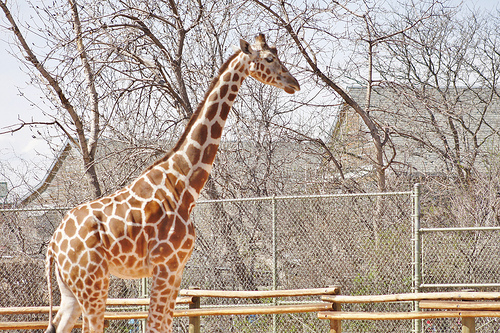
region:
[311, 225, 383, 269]
a gray fence with poles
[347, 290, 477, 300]
brown bleachers near fence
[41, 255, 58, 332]
the tail on giraffe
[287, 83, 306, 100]
mouth on the giraffe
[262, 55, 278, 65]
an eye on the giraffe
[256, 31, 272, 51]
one of the giraffe's ears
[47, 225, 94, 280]
hind area of giraffe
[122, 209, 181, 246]
portion of giraffe's spots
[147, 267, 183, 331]
front legs of giraffe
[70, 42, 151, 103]
some bare tree branches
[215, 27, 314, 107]
head of a giraffe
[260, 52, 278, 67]
eye of a giraffe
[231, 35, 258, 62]
ear of a giraffe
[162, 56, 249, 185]
neck of a giraffe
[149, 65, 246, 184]
long neck of a giraffe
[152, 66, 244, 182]
spotted neck of a giraffe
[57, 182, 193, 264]
body of a giraffe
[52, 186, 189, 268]
spotted body of a giraffe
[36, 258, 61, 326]
tail of a giraffe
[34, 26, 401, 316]
giraffe outside in daylight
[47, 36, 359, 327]
large giraffe standing in enclosure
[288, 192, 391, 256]
metal fence enclosure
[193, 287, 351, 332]
fence made of brown wood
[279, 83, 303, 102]
mouth of giraffe is slightly open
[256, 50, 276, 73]
side eye of giraffe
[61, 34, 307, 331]
giraffe is looking right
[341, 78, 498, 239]
house is in background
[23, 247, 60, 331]
tail of orange and cream giraffe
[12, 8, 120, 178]
trees without any leaves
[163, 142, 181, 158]
mohawk hair of giraffe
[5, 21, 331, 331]
a young adult giraffe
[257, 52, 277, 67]
the giraffe's right eye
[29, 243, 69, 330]
the tail of the giraffe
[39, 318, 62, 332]
ball looking thing on the bottom of the giraffe's tail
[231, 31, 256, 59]
the giraffe's right ear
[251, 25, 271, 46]
horn on the giraffe's head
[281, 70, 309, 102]
the mouth of the giraffe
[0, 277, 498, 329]
a wooden fence behind the giraffe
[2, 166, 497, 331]
chain link fence behind the giraffe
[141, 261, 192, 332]
The giraffe's right leg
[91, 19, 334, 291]
giraffe is looking to the left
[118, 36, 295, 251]
the neck is long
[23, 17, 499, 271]
the trees are bare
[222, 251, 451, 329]
shorter fence is made of wood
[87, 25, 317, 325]
the giraffe is brown and white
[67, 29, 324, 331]
a spotter pattern of giraffe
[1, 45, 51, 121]
the sky is clear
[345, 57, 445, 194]
the roof is light green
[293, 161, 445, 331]
the fence is made of wires